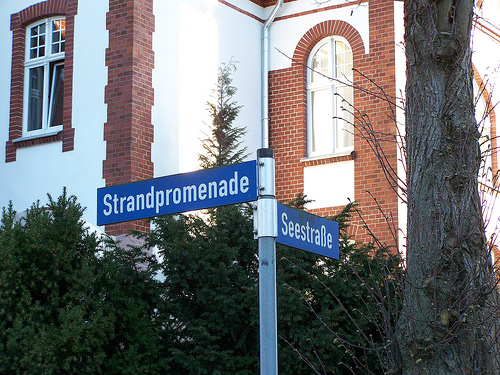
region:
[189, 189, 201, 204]
Blue street sign on the pole.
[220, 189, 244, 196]
Blue street sign on the pole.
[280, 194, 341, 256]
Blue street sign on the pole.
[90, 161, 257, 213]
Blue street sign on the pole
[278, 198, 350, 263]
Blue street sign on the pole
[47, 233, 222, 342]
leaves on a tree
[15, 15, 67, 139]
Open window on the building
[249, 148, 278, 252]
bracket on street pole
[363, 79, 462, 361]
small branches on a tree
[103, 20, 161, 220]
Bricks on a build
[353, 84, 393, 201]
Bricks on a build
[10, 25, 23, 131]
Bricks on a build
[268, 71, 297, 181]
Bricks on a build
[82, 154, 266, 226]
blue and white street sign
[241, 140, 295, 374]
metal street sign support pole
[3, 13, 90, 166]
window on side of white building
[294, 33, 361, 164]
arched white framed window on side of building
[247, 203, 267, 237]
metal bolts on street sign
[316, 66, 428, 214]
bare brown tree branches on side of tree trunk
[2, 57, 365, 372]
green bushes and trees in front of building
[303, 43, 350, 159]
white light reflecting on windows on house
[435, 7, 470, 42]
black hole on side of tree trunk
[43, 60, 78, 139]
open window pane on window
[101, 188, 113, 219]
The letter is white.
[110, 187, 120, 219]
The letter is white.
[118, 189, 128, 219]
The letter is white.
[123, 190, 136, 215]
The letter is white.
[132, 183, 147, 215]
The letter is white.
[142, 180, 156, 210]
The letter is white.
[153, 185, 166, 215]
The letter is white.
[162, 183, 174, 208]
The letter is white.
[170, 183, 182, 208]
The letter is white.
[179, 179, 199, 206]
The letter is white.